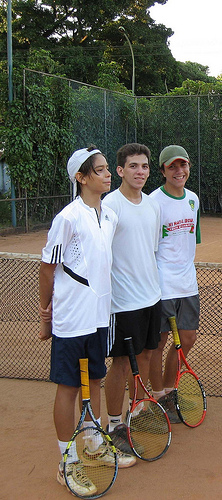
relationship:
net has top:
[2, 250, 221, 397] [1, 251, 221, 267]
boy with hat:
[40, 144, 137, 494] [67, 144, 103, 200]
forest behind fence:
[3, 1, 222, 231] [3, 63, 221, 215]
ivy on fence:
[3, 98, 37, 210] [3, 63, 221, 215]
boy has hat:
[40, 144, 137, 494] [67, 144, 103, 200]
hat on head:
[159, 142, 190, 166] [159, 145, 190, 188]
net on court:
[2, 250, 221, 397] [2, 214, 217, 498]